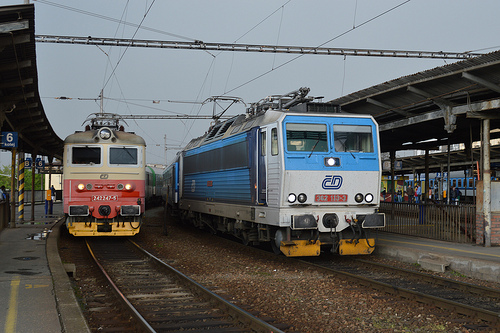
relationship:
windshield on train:
[282, 120, 369, 157] [161, 101, 386, 257]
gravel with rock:
[265, 281, 361, 319] [185, 237, 365, 325]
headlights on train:
[293, 174, 399, 206] [195, 118, 361, 237]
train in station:
[59, 109, 149, 250] [6, 5, 498, 330]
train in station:
[159, 94, 379, 264] [6, 5, 498, 330]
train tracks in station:
[81, 229, 268, 330] [6, 5, 498, 330]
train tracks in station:
[77, 236, 284, 330] [6, 5, 498, 330]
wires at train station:
[35, 4, 498, 98] [1, 2, 488, 331]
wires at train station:
[35, 22, 498, 67] [26, 31, 498, 76]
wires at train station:
[55, 94, 251, 124] [1, 2, 488, 331]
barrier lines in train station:
[3, 276, 21, 333] [1, 2, 488, 331]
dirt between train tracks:
[135, 209, 480, 330] [68, 191, 498, 331]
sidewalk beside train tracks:
[6, 193, 89, 329] [77, 236, 284, 330]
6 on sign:
[4, 134, 18, 152] [0, 133, 18, 147]